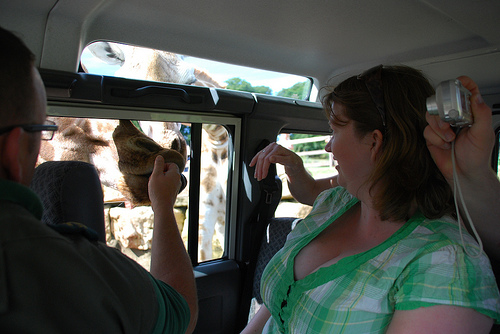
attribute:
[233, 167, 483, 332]
shirt — green